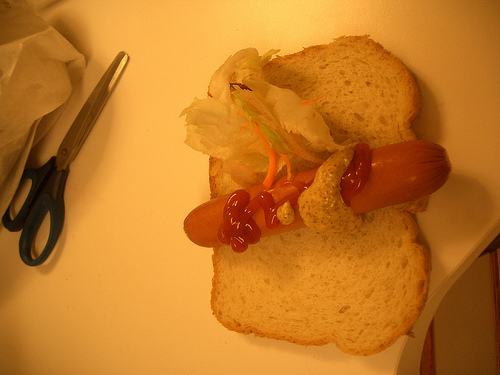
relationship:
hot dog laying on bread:
[183, 136, 450, 253] [207, 45, 432, 359]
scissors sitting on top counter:
[0, 50, 130, 269] [0, 2, 493, 370]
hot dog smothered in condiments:
[183, 136, 450, 253] [191, 145, 383, 249]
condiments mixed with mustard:
[217, 142, 383, 254] [278, 144, 363, 237]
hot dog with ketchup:
[183, 136, 450, 253] [206, 184, 267, 243]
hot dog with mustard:
[183, 136, 450, 253] [286, 154, 357, 248]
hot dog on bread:
[183, 136, 450, 253] [207, 45, 432, 359]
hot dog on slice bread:
[183, 136, 450, 253] [207, 45, 432, 359]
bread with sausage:
[207, 45, 432, 359] [174, 132, 455, 259]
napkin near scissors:
[5, 20, 59, 106] [2, 44, 133, 269]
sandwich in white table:
[175, 37, 443, 370] [2, 1, 498, 373]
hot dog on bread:
[178, 128, 458, 253] [207, 45, 432, 359]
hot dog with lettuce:
[183, 136, 450, 253] [174, 43, 349, 183]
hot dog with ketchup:
[183, 136, 450, 253] [216, 143, 373, 253]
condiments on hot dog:
[217, 142, 383, 254] [183, 136, 450, 253]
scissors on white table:
[2, 44, 133, 269] [2, 1, 498, 373]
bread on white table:
[207, 45, 432, 359] [2, 1, 498, 373]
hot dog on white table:
[183, 136, 450, 253] [2, 1, 498, 373]